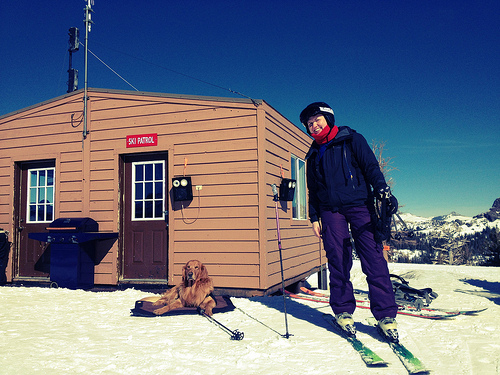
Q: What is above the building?
A: Blue sky.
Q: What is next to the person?
A: Ski pole.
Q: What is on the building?
A: The door.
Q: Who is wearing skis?
A: Woman next to building.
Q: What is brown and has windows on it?
A: Doors.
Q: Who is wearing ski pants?
A: Woman outside.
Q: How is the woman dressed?
A: Warm.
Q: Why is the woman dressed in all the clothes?
A: To keep warm.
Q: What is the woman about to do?
A: Ski.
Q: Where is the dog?
A: Lying next to building.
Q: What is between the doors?
A: Grill.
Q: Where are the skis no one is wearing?
A: Behind woman on skis.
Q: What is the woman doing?
A: Skiing.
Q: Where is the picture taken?
A: In the mountains.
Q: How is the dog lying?
A: On a blanket with a ski pole in front of him.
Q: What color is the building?
A: Brown.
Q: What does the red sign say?
A: Ski Patrol.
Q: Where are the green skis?
A: On the woman's foot.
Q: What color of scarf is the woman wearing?
A: Red.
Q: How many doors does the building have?
A: Two.